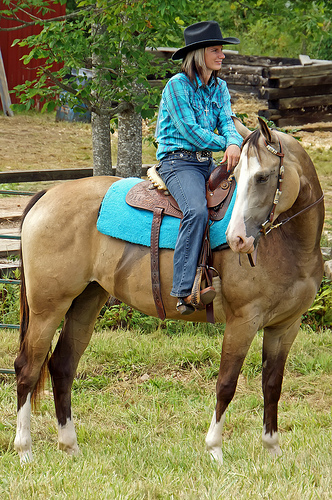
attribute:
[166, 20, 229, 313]
woman — young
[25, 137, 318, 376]
horse — beige, tan, brown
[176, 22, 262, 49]
hat — black, cowboy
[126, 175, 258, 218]
saddle — brown, leather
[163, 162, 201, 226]
jeans — blue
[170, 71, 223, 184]
blue shirt — plaid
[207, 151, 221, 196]
saddle strap — brown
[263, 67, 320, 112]
wooden fence — gray, split rail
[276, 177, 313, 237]
bridle — brown leather